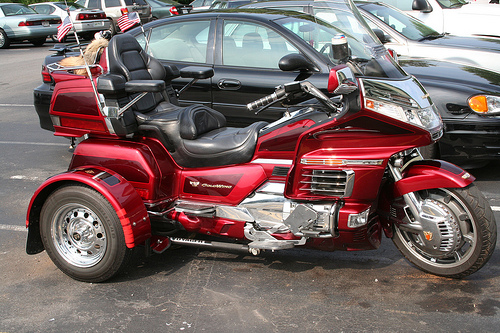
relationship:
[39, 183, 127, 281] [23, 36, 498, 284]
tire on bike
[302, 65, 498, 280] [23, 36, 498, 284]
front section of bike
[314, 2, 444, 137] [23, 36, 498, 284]
guard on bike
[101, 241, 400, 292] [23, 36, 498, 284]
shade under bike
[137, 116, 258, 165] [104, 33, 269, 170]
edge of seat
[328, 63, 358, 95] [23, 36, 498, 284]
mirror on side of bike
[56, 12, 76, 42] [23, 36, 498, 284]
flag on top of bike